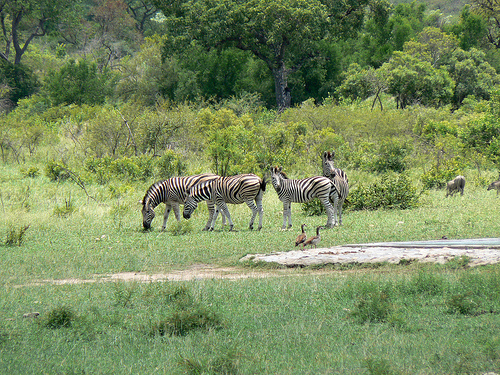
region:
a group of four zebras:
[119, 148, 386, 249]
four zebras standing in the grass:
[105, 146, 356, 234]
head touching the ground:
[133, 196, 158, 235]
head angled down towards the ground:
[176, 187, 203, 222]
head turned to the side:
[269, 166, 290, 192]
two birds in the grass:
[287, 218, 332, 255]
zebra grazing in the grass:
[111, 164, 215, 234]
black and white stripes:
[286, 171, 329, 203]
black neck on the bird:
[315, 225, 324, 237]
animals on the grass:
[110, 131, 395, 268]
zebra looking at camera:
[263, 163, 347, 241]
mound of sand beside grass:
[239, 243, 499, 270]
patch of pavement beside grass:
[351, 235, 498, 250]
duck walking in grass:
[303, 217, 327, 252]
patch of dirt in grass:
[11, 250, 422, 286]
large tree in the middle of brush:
[150, 1, 371, 123]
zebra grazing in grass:
[129, 162, 230, 234]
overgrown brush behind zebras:
[16, 90, 498, 215]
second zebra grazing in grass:
[176, 170, 270, 234]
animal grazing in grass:
[440, 171, 475, 204]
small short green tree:
[93, 163, 120, 195]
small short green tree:
[52, 196, 78, 229]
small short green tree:
[439, 128, 452, 165]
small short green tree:
[323, 128, 352, 163]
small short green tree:
[283, 133, 314, 175]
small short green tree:
[223, 146, 245, 180]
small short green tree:
[347, 283, 386, 320]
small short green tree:
[158, 313, 191, 347]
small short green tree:
[41, 308, 68, 329]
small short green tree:
[43, 159, 68, 178]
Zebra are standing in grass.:
[134, 148, 367, 255]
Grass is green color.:
[44, 214, 129, 259]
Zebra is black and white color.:
[140, 156, 337, 233]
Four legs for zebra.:
[206, 197, 270, 237]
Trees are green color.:
[63, 25, 393, 94]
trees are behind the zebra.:
[47, 20, 347, 229]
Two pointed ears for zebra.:
[316, 148, 346, 163]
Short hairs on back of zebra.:
[138, 168, 177, 200]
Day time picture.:
[26, 48, 476, 366]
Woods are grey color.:
[261, 38, 308, 112]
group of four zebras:
[112, 135, 385, 241]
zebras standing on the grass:
[111, 150, 361, 232]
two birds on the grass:
[287, 224, 327, 246]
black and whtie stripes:
[282, 176, 326, 201]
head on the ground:
[128, 190, 163, 230]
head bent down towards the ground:
[175, 186, 204, 223]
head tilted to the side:
[262, 164, 284, 188]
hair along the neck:
[132, 183, 164, 208]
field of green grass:
[2, 222, 494, 374]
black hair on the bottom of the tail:
[329, 176, 347, 210]